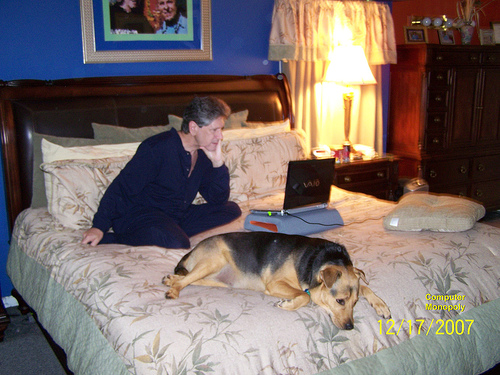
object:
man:
[81, 93, 243, 247]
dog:
[161, 224, 393, 331]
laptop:
[249, 156, 335, 218]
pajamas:
[87, 127, 230, 219]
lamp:
[322, 42, 378, 161]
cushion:
[382, 190, 485, 234]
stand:
[247, 212, 347, 235]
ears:
[320, 264, 340, 288]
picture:
[76, 0, 214, 65]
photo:
[0, 2, 498, 374]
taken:
[377, 291, 483, 338]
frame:
[2, 72, 294, 242]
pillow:
[220, 127, 305, 200]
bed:
[0, 79, 497, 374]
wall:
[2, 0, 284, 79]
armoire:
[387, 39, 500, 214]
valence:
[0, 197, 498, 374]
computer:
[425, 291, 464, 304]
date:
[376, 316, 479, 338]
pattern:
[134, 338, 169, 366]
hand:
[201, 139, 223, 166]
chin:
[198, 140, 225, 157]